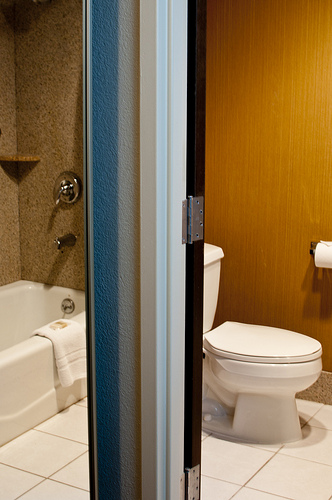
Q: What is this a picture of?
A: A bathroom.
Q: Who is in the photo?
A: No one.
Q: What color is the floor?
A: White.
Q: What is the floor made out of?
A: Tile.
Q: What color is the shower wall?
A: Brown.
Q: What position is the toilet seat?
A: Down.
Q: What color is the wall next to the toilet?
A: Brown.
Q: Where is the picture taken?
A: In a bathroom.